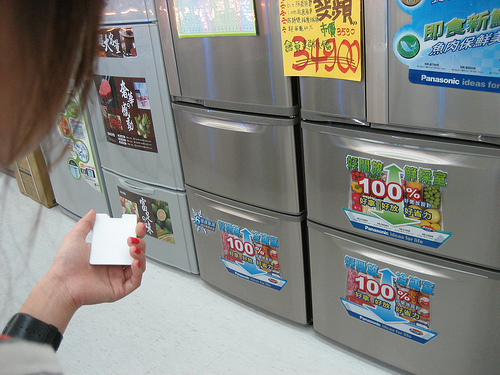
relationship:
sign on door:
[338, 148, 456, 250] [296, 120, 500, 263]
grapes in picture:
[425, 184, 443, 210] [338, 148, 456, 250]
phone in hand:
[86, 201, 141, 271] [45, 200, 158, 314]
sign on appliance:
[338, 148, 456, 250] [155, 0, 499, 375]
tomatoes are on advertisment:
[346, 167, 365, 213] [338, 148, 456, 250]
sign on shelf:
[338, 148, 456, 250] [155, 0, 499, 375]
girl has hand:
[1, 4, 153, 375] [45, 200, 158, 314]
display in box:
[277, 1, 363, 80] [272, 2, 376, 121]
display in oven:
[338, 148, 456, 250] [296, 120, 500, 263]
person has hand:
[1, 4, 153, 375] [45, 200, 158, 314]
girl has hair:
[1, 4, 153, 375] [2, 1, 115, 243]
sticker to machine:
[189, 205, 291, 296] [183, 184, 313, 329]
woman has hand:
[1, 4, 153, 375] [45, 200, 158, 314]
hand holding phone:
[45, 200, 158, 314] [86, 201, 141, 271]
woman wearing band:
[1, 4, 153, 375] [2, 307, 70, 350]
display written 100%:
[338, 148, 456, 250] [355, 171, 430, 206]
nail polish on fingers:
[132, 230, 145, 269] [124, 240, 148, 300]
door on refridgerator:
[85, 22, 198, 279] [68, 1, 202, 281]